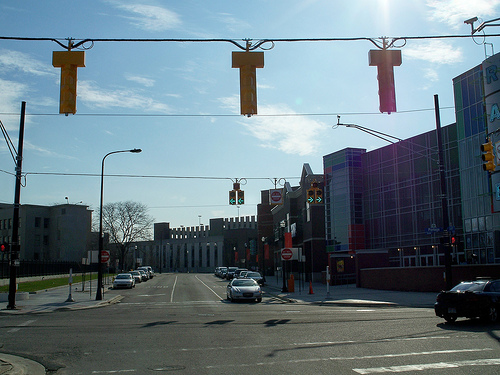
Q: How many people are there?
A: None.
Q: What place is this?
A: Intersection.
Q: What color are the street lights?
A: Yellow.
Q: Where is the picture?
A: City.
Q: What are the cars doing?
A: Driving.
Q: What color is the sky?
A: Blue.